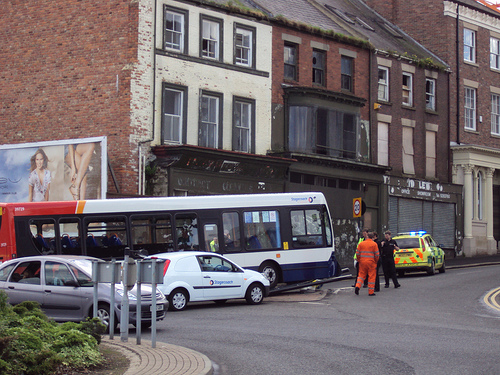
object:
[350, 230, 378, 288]
man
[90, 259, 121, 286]
sign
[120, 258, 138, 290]
sign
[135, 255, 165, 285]
sign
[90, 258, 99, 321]
pole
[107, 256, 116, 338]
pole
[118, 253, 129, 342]
pole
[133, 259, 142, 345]
pole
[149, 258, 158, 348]
pole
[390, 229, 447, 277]
car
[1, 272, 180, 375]
corner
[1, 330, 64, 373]
bush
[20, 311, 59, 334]
bush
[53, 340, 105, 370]
bush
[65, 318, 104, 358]
bush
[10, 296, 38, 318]
bush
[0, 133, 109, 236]
billboard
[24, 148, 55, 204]
woman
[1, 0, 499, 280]
apartment building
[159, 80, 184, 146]
window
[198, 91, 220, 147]
window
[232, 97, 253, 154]
window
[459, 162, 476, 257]
pillar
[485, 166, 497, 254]
pillar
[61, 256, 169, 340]
signs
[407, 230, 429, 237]
lights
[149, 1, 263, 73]
windows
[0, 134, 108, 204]
ad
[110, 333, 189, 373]
stones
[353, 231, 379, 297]
man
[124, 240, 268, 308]
car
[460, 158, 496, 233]
columns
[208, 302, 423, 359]
paving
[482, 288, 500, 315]
lines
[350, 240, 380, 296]
jumpsuit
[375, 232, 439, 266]
bar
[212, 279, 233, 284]
lettering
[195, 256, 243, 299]
door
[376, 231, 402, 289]
man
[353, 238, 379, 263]
clothes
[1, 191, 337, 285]
bus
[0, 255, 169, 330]
car